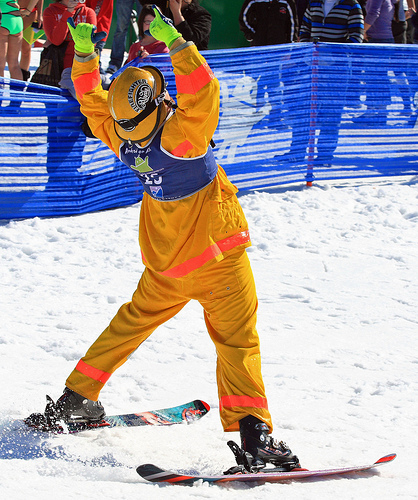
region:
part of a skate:
[256, 401, 257, 416]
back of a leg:
[226, 362, 233, 369]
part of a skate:
[379, 460, 387, 472]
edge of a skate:
[241, 459, 249, 488]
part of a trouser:
[226, 361, 234, 410]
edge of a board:
[257, 464, 268, 491]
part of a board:
[119, 385, 121, 401]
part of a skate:
[268, 448, 282, 461]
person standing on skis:
[21, 4, 397, 488]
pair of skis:
[20, 380, 401, 489]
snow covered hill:
[6, 185, 410, 499]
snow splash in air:
[9, 407, 60, 452]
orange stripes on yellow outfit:
[215, 388, 275, 412]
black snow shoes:
[34, 376, 306, 473]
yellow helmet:
[100, 62, 170, 147]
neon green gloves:
[57, 3, 187, 55]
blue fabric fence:
[2, 35, 415, 232]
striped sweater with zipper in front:
[292, 1, 367, 64]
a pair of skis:
[19, 375, 413, 498]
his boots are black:
[27, 380, 304, 461]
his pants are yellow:
[54, 251, 286, 447]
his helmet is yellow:
[94, 58, 174, 148]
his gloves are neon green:
[57, 3, 190, 51]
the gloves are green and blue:
[43, 0, 211, 62]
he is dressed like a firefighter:
[45, 8, 396, 490]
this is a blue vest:
[108, 122, 245, 205]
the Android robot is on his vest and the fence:
[83, 8, 281, 218]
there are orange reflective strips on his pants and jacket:
[51, 13, 311, 487]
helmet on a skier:
[96, 60, 163, 140]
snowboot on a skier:
[229, 391, 310, 490]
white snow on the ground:
[310, 244, 378, 327]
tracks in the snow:
[274, 206, 340, 290]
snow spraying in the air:
[12, 411, 81, 465]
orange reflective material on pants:
[205, 370, 274, 426]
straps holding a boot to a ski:
[224, 433, 301, 478]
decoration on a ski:
[134, 381, 206, 432]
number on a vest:
[128, 156, 176, 206]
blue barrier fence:
[263, 69, 368, 180]